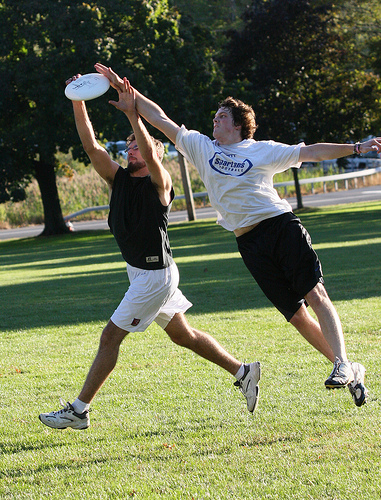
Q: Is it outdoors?
A: Yes, it is outdoors.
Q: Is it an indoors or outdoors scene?
A: It is outdoors.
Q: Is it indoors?
A: No, it is outdoors.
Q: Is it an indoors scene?
A: No, it is outdoors.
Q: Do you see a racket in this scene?
A: No, there are no rackets.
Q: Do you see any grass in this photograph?
A: Yes, there is grass.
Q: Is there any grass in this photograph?
A: Yes, there is grass.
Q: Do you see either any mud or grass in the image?
A: Yes, there is grass.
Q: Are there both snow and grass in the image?
A: No, there is grass but no snow.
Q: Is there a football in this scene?
A: No, there are no footballs.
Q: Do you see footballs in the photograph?
A: No, there are no footballs.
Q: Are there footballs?
A: No, there are no footballs.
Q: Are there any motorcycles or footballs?
A: No, there are no footballs or motorcycles.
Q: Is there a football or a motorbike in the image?
A: No, there are no footballs or motorcycles.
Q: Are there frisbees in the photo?
A: Yes, there is a frisbee.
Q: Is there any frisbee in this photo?
A: Yes, there is a frisbee.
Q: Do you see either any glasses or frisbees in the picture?
A: Yes, there is a frisbee.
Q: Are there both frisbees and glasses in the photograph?
A: Yes, there are both a frisbee and glasses.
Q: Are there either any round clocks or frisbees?
A: Yes, there is a round frisbee.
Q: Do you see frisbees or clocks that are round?
A: Yes, the frisbee is round.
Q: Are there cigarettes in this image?
A: No, there are no cigarettes.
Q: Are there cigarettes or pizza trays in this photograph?
A: No, there are no cigarettes or pizza trays.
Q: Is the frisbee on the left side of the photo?
A: Yes, the frisbee is on the left of the image.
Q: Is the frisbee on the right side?
A: No, the frisbee is on the left of the image.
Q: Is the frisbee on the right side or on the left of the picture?
A: The frisbee is on the left of the image.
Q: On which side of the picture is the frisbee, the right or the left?
A: The frisbee is on the left of the image.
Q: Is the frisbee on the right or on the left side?
A: The frisbee is on the left of the image.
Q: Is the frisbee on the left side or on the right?
A: The frisbee is on the left of the image.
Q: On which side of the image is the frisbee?
A: The frisbee is on the left of the image.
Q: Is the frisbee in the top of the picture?
A: Yes, the frisbee is in the top of the image.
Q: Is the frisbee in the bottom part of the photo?
A: No, the frisbee is in the top of the image.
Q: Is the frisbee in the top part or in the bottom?
A: The frisbee is in the top of the image.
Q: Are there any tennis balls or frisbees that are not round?
A: No, there is a frisbee but it is round.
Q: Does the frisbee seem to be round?
A: Yes, the frisbee is round.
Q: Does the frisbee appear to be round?
A: Yes, the frisbee is round.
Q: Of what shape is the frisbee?
A: The frisbee is round.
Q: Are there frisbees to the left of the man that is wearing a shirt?
A: Yes, there is a frisbee to the left of the man.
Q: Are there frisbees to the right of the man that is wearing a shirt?
A: No, the frisbee is to the left of the man.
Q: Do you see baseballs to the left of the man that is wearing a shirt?
A: No, there is a frisbee to the left of the man.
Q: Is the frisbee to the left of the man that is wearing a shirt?
A: Yes, the frisbee is to the left of the man.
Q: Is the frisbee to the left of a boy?
A: No, the frisbee is to the left of the man.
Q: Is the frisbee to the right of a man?
A: No, the frisbee is to the left of a man.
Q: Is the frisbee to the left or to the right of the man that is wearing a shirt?
A: The frisbee is to the left of the man.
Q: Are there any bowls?
A: No, there are no bowls.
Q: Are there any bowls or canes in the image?
A: No, there are no bowls or canes.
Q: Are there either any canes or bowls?
A: No, there are no bowls or canes.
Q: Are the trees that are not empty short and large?
A: No, the trees are large but tall.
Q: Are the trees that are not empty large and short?
A: No, the trees are large but tall.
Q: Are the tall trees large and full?
A: Yes, the trees are large and full.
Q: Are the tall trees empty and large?
A: No, the trees are large but full.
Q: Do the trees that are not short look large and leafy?
A: Yes, the trees are large and leafy.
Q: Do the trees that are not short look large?
A: Yes, the trees are large.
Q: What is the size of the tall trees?
A: The trees are large.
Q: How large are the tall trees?
A: The trees are large.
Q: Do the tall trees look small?
A: No, the trees are large.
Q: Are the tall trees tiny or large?
A: The trees are large.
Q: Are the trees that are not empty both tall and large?
A: Yes, the trees are tall and large.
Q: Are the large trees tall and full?
A: Yes, the trees are tall and full.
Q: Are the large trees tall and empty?
A: No, the trees are tall but full.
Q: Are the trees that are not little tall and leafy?
A: Yes, the trees are tall and leafy.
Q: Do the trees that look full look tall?
A: Yes, the trees are tall.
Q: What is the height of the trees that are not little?
A: The trees are tall.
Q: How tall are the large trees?
A: The trees are tall.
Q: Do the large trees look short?
A: No, the trees are tall.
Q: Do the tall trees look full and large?
A: Yes, the trees are full and large.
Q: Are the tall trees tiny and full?
A: No, the trees are full but large.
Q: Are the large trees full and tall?
A: Yes, the trees are full and tall.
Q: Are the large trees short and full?
A: No, the trees are full but tall.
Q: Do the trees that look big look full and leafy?
A: Yes, the trees are full and leafy.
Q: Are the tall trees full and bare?
A: No, the trees are full but leafy.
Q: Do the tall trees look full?
A: Yes, the trees are full.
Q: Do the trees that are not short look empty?
A: No, the trees are full.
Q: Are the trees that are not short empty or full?
A: The trees are full.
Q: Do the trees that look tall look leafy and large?
A: Yes, the trees are leafy and large.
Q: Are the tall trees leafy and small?
A: No, the trees are leafy but large.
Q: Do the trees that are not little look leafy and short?
A: No, the trees are leafy but tall.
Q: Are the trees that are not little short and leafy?
A: No, the trees are leafy but tall.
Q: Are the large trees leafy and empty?
A: No, the trees are leafy but full.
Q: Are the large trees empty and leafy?
A: No, the trees are leafy but full.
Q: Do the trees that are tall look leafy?
A: Yes, the trees are leafy.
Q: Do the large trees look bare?
A: No, the trees are leafy.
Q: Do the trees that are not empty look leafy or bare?
A: The trees are leafy.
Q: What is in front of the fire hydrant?
A: The tree is in front of the fire hydrant.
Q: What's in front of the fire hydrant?
A: The tree is in front of the fire hydrant.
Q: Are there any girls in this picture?
A: No, there are no girls.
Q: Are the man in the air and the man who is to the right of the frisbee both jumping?
A: Yes, both the man and the man are jumping.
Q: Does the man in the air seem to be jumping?
A: Yes, the man is jumping.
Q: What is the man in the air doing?
A: The man is jumping.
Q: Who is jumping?
A: The man is jumping.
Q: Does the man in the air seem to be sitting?
A: No, the man is jumping.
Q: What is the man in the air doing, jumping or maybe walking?
A: The man is jumping.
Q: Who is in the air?
A: The man is in the air.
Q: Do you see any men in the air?
A: Yes, there is a man in the air.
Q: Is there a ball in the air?
A: No, there is a man in the air.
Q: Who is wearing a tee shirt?
A: The man is wearing a tee shirt.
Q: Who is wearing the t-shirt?
A: The man is wearing a tee shirt.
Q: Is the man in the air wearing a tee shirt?
A: Yes, the man is wearing a tee shirt.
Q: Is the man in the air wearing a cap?
A: No, the man is wearing a tee shirt.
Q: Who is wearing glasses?
A: The man is wearing glasses.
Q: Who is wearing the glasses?
A: The man is wearing glasses.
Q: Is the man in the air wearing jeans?
A: No, the man is wearing glasses.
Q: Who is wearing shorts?
A: The man is wearing shorts.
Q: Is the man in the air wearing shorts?
A: Yes, the man is wearing shorts.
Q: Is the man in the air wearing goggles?
A: No, the man is wearing shorts.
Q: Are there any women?
A: No, there are no women.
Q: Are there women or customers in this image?
A: No, there are no women or customers.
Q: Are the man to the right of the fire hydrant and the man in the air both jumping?
A: Yes, both the man and the man are jumping.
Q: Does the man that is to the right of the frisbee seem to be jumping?
A: Yes, the man is jumping.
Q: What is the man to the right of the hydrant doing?
A: The man is jumping.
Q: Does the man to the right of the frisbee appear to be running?
A: No, the man is jumping.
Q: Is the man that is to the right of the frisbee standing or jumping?
A: The man is jumping.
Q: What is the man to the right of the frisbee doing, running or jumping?
A: The man is jumping.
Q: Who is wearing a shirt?
A: The man is wearing a shirt.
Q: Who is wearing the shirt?
A: The man is wearing a shirt.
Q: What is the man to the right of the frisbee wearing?
A: The man is wearing a shirt.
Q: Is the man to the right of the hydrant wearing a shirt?
A: Yes, the man is wearing a shirt.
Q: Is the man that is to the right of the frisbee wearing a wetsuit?
A: No, the man is wearing a shirt.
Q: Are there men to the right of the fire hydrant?
A: Yes, there is a man to the right of the fire hydrant.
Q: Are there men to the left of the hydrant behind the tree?
A: No, the man is to the right of the hydrant.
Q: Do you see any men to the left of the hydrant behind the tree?
A: No, the man is to the right of the hydrant.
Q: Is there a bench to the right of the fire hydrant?
A: No, there is a man to the right of the fire hydrant.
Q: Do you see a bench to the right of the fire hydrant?
A: No, there is a man to the right of the fire hydrant.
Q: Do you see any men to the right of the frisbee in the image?
A: Yes, there is a man to the right of the frisbee.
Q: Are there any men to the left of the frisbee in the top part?
A: No, the man is to the right of the frisbee.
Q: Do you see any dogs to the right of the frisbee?
A: No, there is a man to the right of the frisbee.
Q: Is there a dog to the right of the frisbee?
A: No, there is a man to the right of the frisbee.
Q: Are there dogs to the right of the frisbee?
A: No, there is a man to the right of the frisbee.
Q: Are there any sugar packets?
A: No, there are no sugar packets.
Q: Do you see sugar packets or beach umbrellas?
A: No, there are no sugar packets or beach umbrellas.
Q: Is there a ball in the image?
A: No, there are no balls.